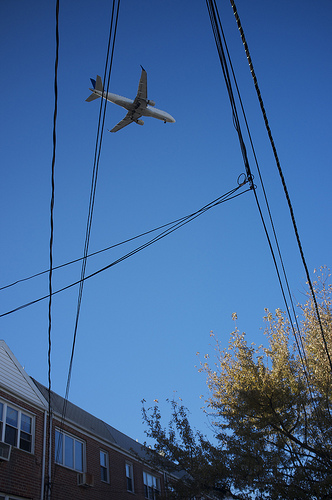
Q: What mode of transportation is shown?
A: Plane.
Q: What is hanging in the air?
A: Utility lines.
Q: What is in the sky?
A: Plane.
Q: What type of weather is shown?
A: Clear.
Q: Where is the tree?
A: Bottom right corner.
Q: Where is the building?
A: Bottom left side.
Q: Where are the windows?
A: Building.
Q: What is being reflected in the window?
A: Sky.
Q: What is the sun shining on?
A: Top of the tree.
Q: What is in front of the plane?
A: Wires.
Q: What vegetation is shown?
A: Tree.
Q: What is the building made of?
A: Bricks.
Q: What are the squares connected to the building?
A: Air conditioners.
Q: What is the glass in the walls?
A: Windows.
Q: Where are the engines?
A: On wings.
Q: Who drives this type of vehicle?
A: Pilot.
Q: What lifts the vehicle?
A: Wings.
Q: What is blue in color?
A: The sky.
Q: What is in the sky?
A: A plane.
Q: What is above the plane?
A: The blue sky.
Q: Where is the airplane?
A: In the sky.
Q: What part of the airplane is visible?
A: The bottom.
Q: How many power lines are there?
A: Nine.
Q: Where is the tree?
A: On the right.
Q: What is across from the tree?
A: A building.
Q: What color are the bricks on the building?
A: Red.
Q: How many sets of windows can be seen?
A: Five.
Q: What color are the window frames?
A: White.